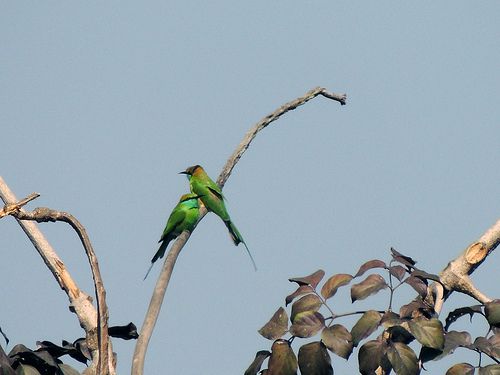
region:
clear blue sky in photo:
[38, 36, 169, 133]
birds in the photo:
[127, 150, 251, 250]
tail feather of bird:
[208, 220, 256, 270]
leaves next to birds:
[258, 249, 365, 349]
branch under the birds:
[104, 262, 201, 359]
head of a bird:
[172, 156, 210, 189]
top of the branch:
[294, 62, 384, 137]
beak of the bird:
[174, 163, 191, 185]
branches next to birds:
[18, 204, 118, 313]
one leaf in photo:
[318, 261, 361, 303]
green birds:
[155, 161, 246, 239]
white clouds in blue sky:
[337, 151, 402, 201]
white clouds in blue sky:
[261, 138, 322, 173]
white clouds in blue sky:
[197, 278, 244, 310]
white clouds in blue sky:
[178, 296, 225, 338]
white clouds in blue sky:
[377, 182, 405, 200]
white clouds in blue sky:
[275, 188, 306, 215]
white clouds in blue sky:
[367, 176, 411, 204]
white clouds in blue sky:
[314, 116, 368, 153]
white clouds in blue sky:
[424, 46, 455, 61]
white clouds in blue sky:
[404, 31, 455, 81]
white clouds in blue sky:
[374, 72, 442, 169]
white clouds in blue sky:
[287, 131, 335, 196]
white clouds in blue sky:
[171, 248, 243, 279]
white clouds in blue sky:
[188, 306, 223, 330]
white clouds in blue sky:
[300, 149, 347, 179]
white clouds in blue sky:
[131, 0, 178, 44]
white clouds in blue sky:
[137, 133, 175, 171]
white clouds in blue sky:
[62, 41, 133, 112]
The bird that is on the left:
[153, 191, 201, 256]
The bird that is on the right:
[180, 156, 245, 256]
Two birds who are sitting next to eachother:
[155, 159, 253, 283]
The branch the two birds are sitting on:
[115, 81, 353, 315]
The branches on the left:
[5, 189, 132, 373]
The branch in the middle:
[122, 81, 347, 368]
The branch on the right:
[309, 223, 491, 364]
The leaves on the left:
[3, 319, 94, 371]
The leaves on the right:
[256, 268, 497, 373]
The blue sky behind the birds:
[9, 3, 483, 373]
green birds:
[130, 148, 272, 303]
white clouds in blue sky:
[404, 143, 472, 187]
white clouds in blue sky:
[187, 313, 208, 334]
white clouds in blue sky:
[95, 65, 160, 115]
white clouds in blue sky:
[14, 58, 65, 99]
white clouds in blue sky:
[361, 31, 411, 81]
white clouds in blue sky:
[134, 38, 184, 90]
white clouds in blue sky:
[67, 75, 122, 129]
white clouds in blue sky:
[64, 22, 121, 76]